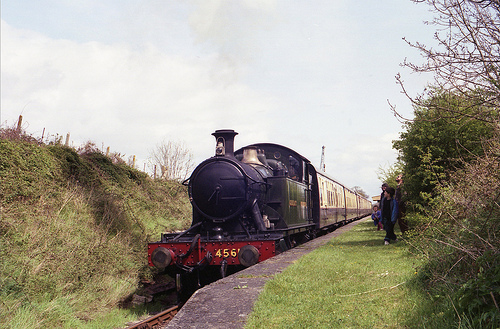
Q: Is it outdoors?
A: Yes, it is outdoors.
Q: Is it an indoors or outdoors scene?
A: It is outdoors.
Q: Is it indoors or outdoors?
A: It is outdoors.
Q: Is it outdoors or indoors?
A: It is outdoors.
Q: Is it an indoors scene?
A: No, it is outdoors.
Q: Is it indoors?
A: No, it is outdoors.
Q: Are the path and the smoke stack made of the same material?
A: No, the path is made of cement and the smoke stack is made of metal.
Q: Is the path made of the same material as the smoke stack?
A: No, the path is made of cement and the smoke stack is made of metal.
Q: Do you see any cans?
A: No, there are no cans.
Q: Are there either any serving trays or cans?
A: No, there are no cans or serving trays.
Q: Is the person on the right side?
A: Yes, the person is on the right of the image.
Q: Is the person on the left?
A: No, the person is on the right of the image.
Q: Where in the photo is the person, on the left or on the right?
A: The person is on the right of the image.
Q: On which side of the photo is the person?
A: The person is on the right of the image.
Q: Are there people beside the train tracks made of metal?
A: Yes, there is a person beside the tracks.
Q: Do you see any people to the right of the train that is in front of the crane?
A: Yes, there is a person to the right of the train.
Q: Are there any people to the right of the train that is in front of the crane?
A: Yes, there is a person to the right of the train.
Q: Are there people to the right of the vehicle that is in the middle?
A: Yes, there is a person to the right of the train.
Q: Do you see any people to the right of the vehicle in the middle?
A: Yes, there is a person to the right of the train.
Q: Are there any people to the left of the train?
A: No, the person is to the right of the train.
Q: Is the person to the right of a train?
A: Yes, the person is to the right of a train.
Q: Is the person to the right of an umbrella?
A: No, the person is to the right of a train.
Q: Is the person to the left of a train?
A: No, the person is to the right of a train.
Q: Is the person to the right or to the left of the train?
A: The person is to the right of the train.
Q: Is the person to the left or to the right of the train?
A: The person is to the right of the train.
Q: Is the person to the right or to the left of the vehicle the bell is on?
A: The person is to the right of the train.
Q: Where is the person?
A: The person is in the field.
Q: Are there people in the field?
A: Yes, there is a person in the field.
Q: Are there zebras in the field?
A: No, there is a person in the field.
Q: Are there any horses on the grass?
A: No, there is a person on the grass.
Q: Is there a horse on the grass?
A: No, there is a person on the grass.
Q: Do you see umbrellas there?
A: No, there are no umbrellas.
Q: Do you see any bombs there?
A: No, there are no bombs.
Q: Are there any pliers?
A: No, there are no pliers.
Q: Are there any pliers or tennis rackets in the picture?
A: No, there are no pliers or tennis rackets.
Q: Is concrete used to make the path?
A: Yes, the path is made of concrete.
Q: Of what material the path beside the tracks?
A: The path is made of cement.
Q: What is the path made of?
A: The path is made of concrete.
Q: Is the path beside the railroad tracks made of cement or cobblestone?
A: The path is made of cement.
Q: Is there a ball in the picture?
A: No, there are no balls.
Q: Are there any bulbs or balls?
A: No, there are no balls or bulbs.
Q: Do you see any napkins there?
A: No, there are no napkins.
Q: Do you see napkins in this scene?
A: No, there are no napkins.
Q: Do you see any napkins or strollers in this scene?
A: No, there are no napkins or strollers.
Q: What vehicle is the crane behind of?
A: The crane is behind the train.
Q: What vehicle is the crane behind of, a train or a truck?
A: The crane is behind a train.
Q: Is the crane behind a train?
A: Yes, the crane is behind a train.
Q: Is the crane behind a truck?
A: No, the crane is behind a train.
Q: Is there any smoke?
A: Yes, there is smoke.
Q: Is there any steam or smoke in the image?
A: Yes, there is smoke.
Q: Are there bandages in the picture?
A: No, there are no bandages.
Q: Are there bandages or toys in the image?
A: No, there are no bandages or toys.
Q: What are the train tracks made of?
A: The tracks are made of metal.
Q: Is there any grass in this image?
A: Yes, there is grass.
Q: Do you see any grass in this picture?
A: Yes, there is grass.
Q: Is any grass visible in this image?
A: Yes, there is grass.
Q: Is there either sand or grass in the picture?
A: Yes, there is grass.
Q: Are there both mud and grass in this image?
A: No, there is grass but no mud.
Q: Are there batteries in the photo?
A: No, there are no batteries.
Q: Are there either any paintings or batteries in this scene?
A: No, there are no batteries or paintings.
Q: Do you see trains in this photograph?
A: Yes, there is a train.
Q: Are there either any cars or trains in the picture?
A: Yes, there is a train.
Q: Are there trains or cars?
A: Yes, there is a train.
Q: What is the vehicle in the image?
A: The vehicle is a train.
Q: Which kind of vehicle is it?
A: The vehicle is a train.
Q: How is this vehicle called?
A: That is a train.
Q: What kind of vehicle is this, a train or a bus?
A: That is a train.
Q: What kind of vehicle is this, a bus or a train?
A: That is a train.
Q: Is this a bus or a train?
A: This is a train.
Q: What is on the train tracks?
A: The train is on the train tracks.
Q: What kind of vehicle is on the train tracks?
A: The vehicle is a train.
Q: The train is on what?
A: The train is on the train tracks.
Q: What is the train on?
A: The train is on the train tracks.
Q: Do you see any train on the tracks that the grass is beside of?
A: Yes, there is a train on the tracks.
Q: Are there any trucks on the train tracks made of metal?
A: No, there is a train on the railroad tracks.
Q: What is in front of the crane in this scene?
A: The train is in front of the crane.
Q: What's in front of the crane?
A: The train is in front of the crane.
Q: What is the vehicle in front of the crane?
A: The vehicle is a train.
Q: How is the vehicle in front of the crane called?
A: The vehicle is a train.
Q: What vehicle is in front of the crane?
A: The vehicle is a train.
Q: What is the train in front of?
A: The train is in front of the crane.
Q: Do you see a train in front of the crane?
A: Yes, there is a train in front of the crane.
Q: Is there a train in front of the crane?
A: Yes, there is a train in front of the crane.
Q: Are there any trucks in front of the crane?
A: No, there is a train in front of the crane.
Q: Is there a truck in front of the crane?
A: No, there is a train in front of the crane.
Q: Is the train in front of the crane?
A: Yes, the train is in front of the crane.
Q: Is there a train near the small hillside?
A: Yes, there is a train near the hill side.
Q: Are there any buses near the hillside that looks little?
A: No, there is a train near the hillside.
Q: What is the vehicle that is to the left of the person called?
A: The vehicle is a train.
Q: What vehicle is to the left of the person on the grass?
A: The vehicle is a train.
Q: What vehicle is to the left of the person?
A: The vehicle is a train.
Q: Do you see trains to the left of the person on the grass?
A: Yes, there is a train to the left of the person.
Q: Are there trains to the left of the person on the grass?
A: Yes, there is a train to the left of the person.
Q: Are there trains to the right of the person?
A: No, the train is to the left of the person.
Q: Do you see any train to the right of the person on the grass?
A: No, the train is to the left of the person.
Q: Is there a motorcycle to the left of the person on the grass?
A: No, there is a train to the left of the person.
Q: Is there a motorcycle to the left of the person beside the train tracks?
A: No, there is a train to the left of the person.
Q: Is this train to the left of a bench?
A: No, the train is to the left of the person.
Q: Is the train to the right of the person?
A: No, the train is to the left of the person.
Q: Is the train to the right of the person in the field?
A: No, the train is to the left of the person.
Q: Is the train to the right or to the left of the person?
A: The train is to the left of the person.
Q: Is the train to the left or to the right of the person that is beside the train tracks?
A: The train is to the left of the person.